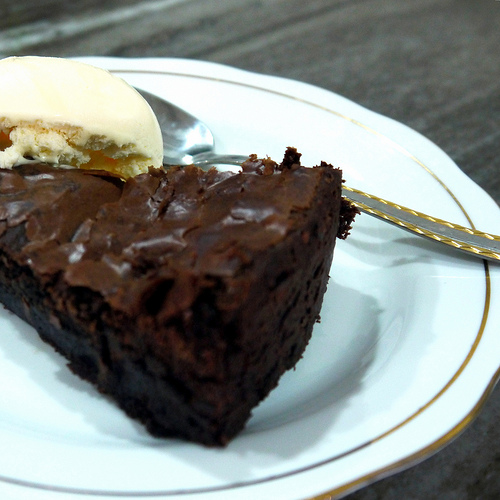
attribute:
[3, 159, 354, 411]
cake — chocolate, sliced, dark, brown, dense, baked, dessert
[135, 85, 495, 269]
spoon — silver, rounded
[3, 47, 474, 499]
plate — white, round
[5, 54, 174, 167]
ice cream — white, round, melting, vanilla, frozen, dairy, scooped, cold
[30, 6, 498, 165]
table — grey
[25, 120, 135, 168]
sauce — brown